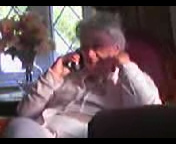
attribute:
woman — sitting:
[3, 10, 162, 140]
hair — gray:
[63, 15, 131, 50]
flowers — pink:
[1, 14, 54, 90]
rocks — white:
[18, 81, 35, 87]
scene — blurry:
[17, 10, 165, 129]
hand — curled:
[108, 52, 130, 67]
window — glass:
[0, 5, 42, 77]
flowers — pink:
[4, 13, 59, 80]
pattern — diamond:
[53, 5, 80, 48]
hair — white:
[74, 15, 127, 51]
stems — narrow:
[24, 67, 33, 84]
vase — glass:
[16, 80, 40, 96]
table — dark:
[1, 87, 37, 117]